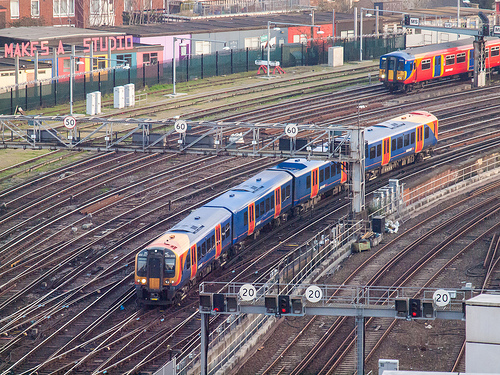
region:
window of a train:
[136, 257, 150, 269]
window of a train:
[163, 256, 176, 278]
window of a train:
[178, 238, 193, 273]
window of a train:
[191, 240, 204, 262]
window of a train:
[196, 236, 208, 259]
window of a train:
[203, 230, 214, 255]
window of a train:
[216, 227, 228, 244]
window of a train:
[238, 211, 252, 233]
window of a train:
[251, 202, 261, 224]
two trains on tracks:
[4, 36, 497, 371]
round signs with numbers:
[239, 284, 451, 306]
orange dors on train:
[247, 185, 284, 235]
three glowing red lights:
[209, 295, 423, 317]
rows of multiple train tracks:
[3, 78, 495, 370]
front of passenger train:
[132, 250, 179, 307]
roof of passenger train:
[148, 108, 435, 253]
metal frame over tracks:
[0, 121, 367, 226]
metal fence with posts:
[0, 35, 404, 112]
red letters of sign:
[5, 34, 132, 58]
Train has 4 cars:
[130, 100, 448, 319]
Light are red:
[197, 276, 470, 328]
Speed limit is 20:
[202, 278, 460, 323]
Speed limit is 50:
[49, 111, 91, 145]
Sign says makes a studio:
[1, 31, 150, 64]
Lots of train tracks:
[16, 79, 481, 371]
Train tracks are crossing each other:
[2, 284, 173, 374]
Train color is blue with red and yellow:
[125, 106, 457, 316]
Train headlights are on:
[133, 249, 184, 313]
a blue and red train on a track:
[123, 115, 438, 315]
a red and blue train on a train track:
[385, 38, 465, 93]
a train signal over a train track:
[271, 291, 297, 321]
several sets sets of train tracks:
[4, 161, 62, 373]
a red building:
[286, 8, 345, 51]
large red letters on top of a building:
[0, 30, 139, 72]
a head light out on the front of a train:
[135, 275, 178, 287]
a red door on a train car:
[208, 219, 225, 260]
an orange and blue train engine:
[133, 208, 231, 309]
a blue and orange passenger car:
[203, 170, 290, 251]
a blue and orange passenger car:
[265, 146, 345, 212]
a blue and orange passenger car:
[357, 110, 437, 176]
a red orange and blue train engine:
[375, 38, 496, 95]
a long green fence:
[0, 30, 408, 111]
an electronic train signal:
[210, 291, 222, 314]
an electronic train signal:
[276, 293, 287, 315]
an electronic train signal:
[408, 295, 420, 320]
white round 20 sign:
[240, 284, 256, 301]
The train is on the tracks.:
[0, 33, 499, 374]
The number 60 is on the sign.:
[171, 117, 299, 139]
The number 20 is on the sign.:
[231, 278, 453, 310]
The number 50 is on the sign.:
[61, 113, 79, 130]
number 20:
[302, 286, 322, 301]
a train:
[139, 244, 179, 296]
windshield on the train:
[134, 258, 152, 278]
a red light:
[278, 302, 287, 314]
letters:
[6, 39, 61, 54]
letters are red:
[3, 40, 63, 65]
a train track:
[103, 305, 169, 350]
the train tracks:
[269, 346, 286, 371]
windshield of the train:
[134, 245, 176, 270]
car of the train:
[223, 169, 287, 235]